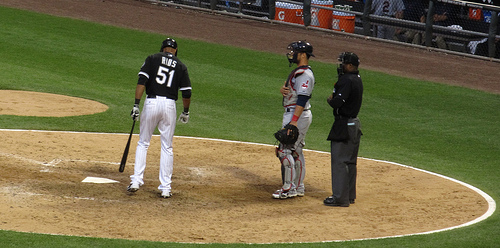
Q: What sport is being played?
A: Baseball.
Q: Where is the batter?
A: Home plate.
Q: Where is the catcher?
A: In front of the umpire.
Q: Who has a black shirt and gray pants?
A: Umpire.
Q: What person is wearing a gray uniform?
A: The catcher.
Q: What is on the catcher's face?
A: A face mask.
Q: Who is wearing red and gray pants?
A: The catcher.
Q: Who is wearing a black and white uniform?
A: The batter.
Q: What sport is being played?
A: Baseball.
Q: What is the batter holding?
A: A baseball bat.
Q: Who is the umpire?
A: The man behind the catcher.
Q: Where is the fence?
A: Next to the field.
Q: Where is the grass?
A: On the field.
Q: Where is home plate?
A: Next to the batter.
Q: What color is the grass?
A: Green.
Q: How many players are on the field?
A: Two.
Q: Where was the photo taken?
A: Baseball game.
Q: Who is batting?
A: Rios.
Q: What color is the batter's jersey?
A: Black and white.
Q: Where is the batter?
A: In the batter's box.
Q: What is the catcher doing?
A: Standing.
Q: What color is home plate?
A: White.